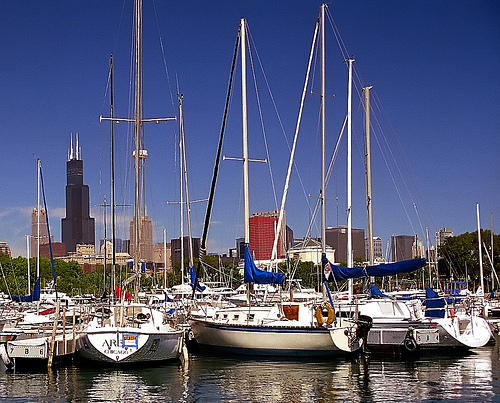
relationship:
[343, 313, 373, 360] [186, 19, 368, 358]
motor on boat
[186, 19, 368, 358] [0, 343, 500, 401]
boat in water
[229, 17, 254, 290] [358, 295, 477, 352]
mast on boat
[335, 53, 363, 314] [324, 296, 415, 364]
pole on boat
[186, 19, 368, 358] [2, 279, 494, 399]
boat in a marina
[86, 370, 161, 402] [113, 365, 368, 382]
reflection of boat on water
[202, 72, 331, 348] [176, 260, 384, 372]
mast on a boat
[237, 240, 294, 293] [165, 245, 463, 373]
sail near a boat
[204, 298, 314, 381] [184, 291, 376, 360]
door of cabin of boat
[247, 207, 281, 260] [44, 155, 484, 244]
building in a city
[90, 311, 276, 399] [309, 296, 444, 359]
masts of boat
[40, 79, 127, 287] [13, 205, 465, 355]
building in distance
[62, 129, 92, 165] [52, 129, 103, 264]
antennas on top of building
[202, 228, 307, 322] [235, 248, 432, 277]
blue sail cover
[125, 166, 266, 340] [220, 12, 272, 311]
white sailboat mast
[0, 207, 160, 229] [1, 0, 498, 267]
cloud against sky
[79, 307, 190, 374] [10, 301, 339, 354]
boat are docked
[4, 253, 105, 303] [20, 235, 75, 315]
leaves are green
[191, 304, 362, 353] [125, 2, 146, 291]
boat have masts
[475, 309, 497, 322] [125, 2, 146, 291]
boat have masts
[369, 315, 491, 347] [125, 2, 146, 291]
boat have masts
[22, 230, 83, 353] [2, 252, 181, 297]
part of a forest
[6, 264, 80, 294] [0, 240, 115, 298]
part of a forest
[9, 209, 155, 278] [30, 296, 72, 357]
edge of a building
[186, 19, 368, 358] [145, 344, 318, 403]
boat in water